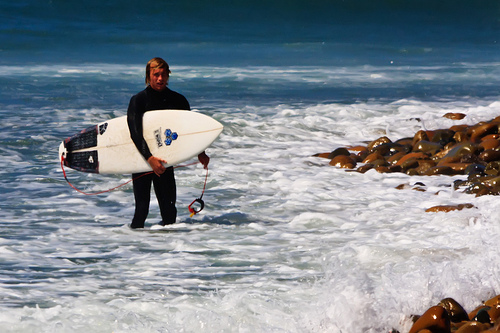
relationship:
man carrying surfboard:
[62, 50, 234, 217] [56, 109, 223, 174]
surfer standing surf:
[127, 57, 212, 229] [92, 210, 335, 300]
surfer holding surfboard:
[127, 57, 212, 229] [56, 109, 223, 174]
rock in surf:
[438, 142, 489, 164] [251, 148, 484, 331]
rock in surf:
[414, 130, 444, 152] [251, 148, 484, 331]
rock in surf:
[395, 151, 435, 178] [251, 148, 484, 331]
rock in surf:
[367, 135, 393, 158] [251, 148, 484, 331]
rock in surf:
[329, 146, 357, 171] [251, 148, 484, 331]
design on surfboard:
[164, 128, 177, 148] [56, 109, 223, 174]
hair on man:
[138, 57, 177, 86] [62, 50, 234, 217]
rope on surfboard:
[58, 154, 129, 194] [61, 111, 224, 166]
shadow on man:
[182, 207, 243, 227] [62, 50, 234, 217]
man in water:
[62, 50, 234, 217] [0, 0, 499, 332]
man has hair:
[62, 50, 234, 217] [125, 32, 192, 72]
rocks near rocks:
[391, 295, 498, 332] [311, 112, 498, 212]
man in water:
[62, 50, 234, 217] [197, 2, 498, 111]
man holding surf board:
[62, 50, 234, 217] [27, 112, 214, 180]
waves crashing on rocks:
[3, 92, 498, 327] [313, 110, 498, 332]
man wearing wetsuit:
[62, 50, 234, 217] [126, 86, 196, 226]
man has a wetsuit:
[62, 50, 234, 217] [125, 81, 182, 226]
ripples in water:
[1, 97, 499, 331] [0, 0, 499, 332]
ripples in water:
[186, 252, 267, 289] [25, 32, 496, 278]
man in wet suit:
[62, 50, 234, 217] [125, 82, 209, 230]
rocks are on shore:
[295, 83, 464, 198] [314, 88, 498, 201]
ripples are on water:
[9, 280, 60, 322] [25, 228, 431, 313]